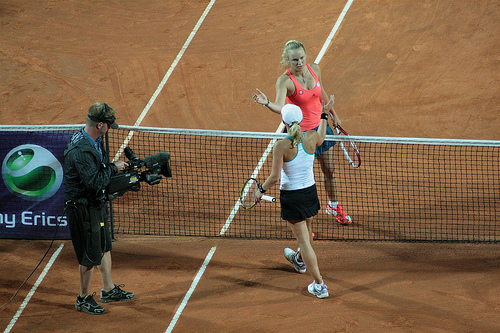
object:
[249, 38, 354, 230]
woman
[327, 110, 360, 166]
tennis racquet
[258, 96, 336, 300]
woman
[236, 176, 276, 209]
tennis racquet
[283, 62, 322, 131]
tank top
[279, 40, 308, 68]
hair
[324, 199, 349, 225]
shoes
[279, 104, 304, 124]
ball cap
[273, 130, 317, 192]
tank top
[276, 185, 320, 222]
black skirt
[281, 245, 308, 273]
tennis shoes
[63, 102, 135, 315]
man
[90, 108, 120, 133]
visor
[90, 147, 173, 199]
camera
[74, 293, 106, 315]
tennis shoes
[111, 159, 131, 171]
hand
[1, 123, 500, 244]
net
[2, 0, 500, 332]
ground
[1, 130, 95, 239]
display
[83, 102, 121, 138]
head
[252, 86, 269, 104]
hand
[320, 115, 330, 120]
wrist band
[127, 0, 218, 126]
line